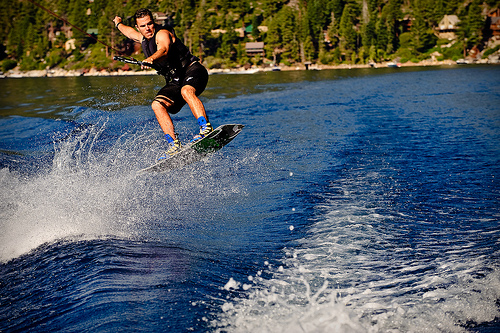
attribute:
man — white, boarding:
[94, 11, 269, 163]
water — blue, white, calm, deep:
[19, 87, 447, 297]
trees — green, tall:
[8, 4, 491, 64]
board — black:
[129, 127, 245, 178]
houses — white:
[176, 7, 293, 61]